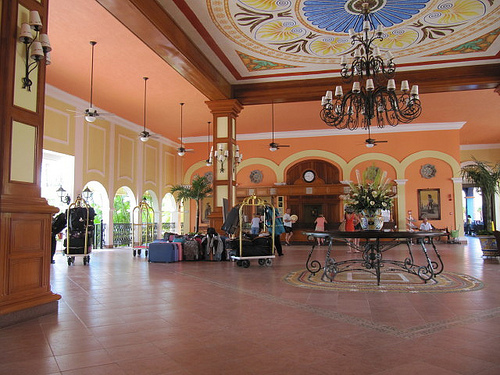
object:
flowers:
[338, 161, 398, 217]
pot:
[361, 216, 384, 231]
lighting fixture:
[17, 8, 52, 92]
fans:
[65, 105, 115, 123]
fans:
[133, 130, 163, 143]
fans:
[169, 146, 196, 157]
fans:
[257, 141, 290, 152]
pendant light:
[177, 103, 185, 158]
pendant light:
[268, 97, 279, 152]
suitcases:
[200, 232, 223, 262]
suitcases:
[69, 209, 85, 230]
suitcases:
[63, 233, 91, 247]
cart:
[63, 195, 96, 265]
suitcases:
[156, 241, 183, 261]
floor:
[1, 237, 496, 372]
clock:
[302, 171, 315, 183]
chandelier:
[319, 10, 423, 130]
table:
[300, 231, 447, 286]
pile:
[144, 228, 237, 263]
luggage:
[148, 242, 179, 263]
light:
[177, 151, 185, 157]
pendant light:
[84, 43, 97, 123]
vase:
[359, 215, 384, 230]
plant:
[343, 162, 398, 217]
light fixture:
[84, 41, 96, 124]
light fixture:
[139, 77, 149, 142]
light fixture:
[176, 103, 187, 157]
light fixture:
[267, 101, 280, 152]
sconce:
[29, 41, 45, 62]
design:
[284, 262, 480, 295]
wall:
[0, 0, 470, 242]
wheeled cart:
[131, 197, 156, 258]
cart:
[219, 193, 276, 269]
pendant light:
[139, 77, 150, 142]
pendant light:
[365, 127, 374, 148]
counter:
[285, 221, 397, 245]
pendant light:
[205, 120, 213, 167]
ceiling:
[46, 0, 496, 125]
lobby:
[2, 1, 500, 375]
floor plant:
[456, 150, 500, 233]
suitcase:
[219, 203, 244, 234]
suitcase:
[264, 205, 286, 235]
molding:
[40, 79, 188, 157]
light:
[83, 115, 97, 123]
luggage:
[235, 237, 273, 258]